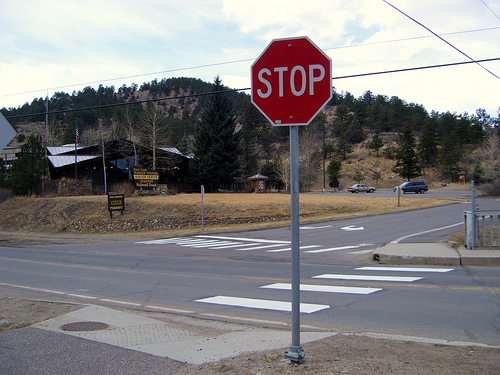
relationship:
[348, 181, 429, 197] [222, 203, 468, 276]
cars on road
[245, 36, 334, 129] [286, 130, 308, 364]
sign on post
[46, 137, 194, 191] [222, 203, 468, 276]
building across road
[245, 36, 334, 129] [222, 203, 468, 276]
sign on road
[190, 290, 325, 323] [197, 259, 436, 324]
stripes on cross walk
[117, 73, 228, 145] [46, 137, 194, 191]
hill behind building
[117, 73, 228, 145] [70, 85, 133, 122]
hill with trees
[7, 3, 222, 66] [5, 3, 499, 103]
clouds in sky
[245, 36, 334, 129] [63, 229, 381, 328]
sign at intersection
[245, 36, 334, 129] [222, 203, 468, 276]
sign next to road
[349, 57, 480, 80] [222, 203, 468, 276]
wire above road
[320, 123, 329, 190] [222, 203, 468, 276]
pole across road